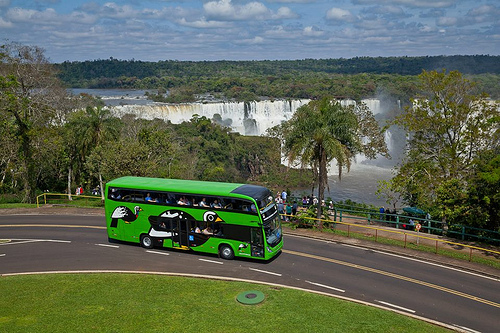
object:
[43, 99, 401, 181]
large waterfall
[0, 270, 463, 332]
grass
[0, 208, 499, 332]
street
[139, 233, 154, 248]
wheel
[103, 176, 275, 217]
second story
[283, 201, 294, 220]
people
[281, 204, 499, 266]
sidewalk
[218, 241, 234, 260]
wheel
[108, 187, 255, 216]
windows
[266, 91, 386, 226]
tree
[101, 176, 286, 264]
bus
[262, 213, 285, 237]
window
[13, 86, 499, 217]
lake